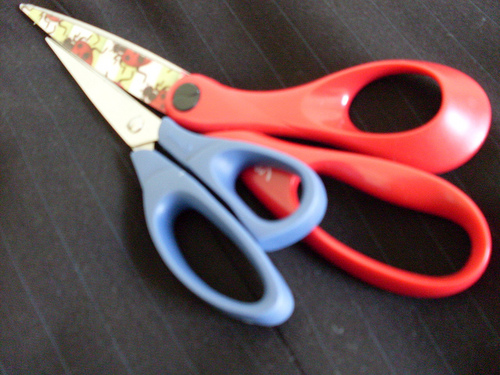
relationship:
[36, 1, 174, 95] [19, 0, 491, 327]
design in scissors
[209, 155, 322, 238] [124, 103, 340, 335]
hole in handle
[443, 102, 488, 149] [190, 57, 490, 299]
light reflection seen in handle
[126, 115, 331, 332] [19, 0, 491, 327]
blue handles of scissors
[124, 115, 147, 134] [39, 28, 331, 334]
bolt on scissors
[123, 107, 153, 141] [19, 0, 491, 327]
bolt on scissors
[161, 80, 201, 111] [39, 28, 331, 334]
bolt on scissors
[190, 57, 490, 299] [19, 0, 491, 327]
handle on scissors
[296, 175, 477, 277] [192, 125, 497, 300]
hole on scissor handle